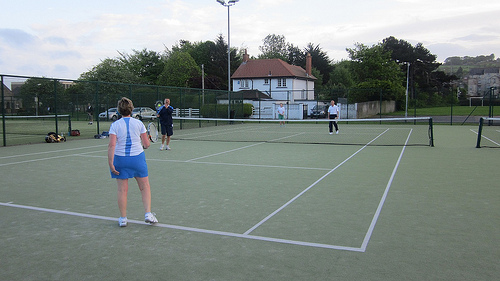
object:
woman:
[107, 97, 158, 226]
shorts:
[111, 151, 148, 179]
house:
[231, 52, 317, 117]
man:
[157, 99, 174, 151]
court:
[0, 118, 499, 280]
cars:
[99, 108, 122, 121]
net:
[174, 118, 431, 146]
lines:
[244, 129, 389, 235]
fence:
[0, 76, 229, 147]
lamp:
[217, 0, 240, 91]